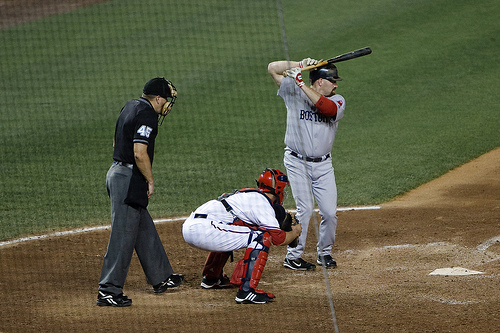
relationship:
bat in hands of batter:
[300, 46, 372, 71] [268, 57, 343, 272]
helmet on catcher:
[256, 168, 289, 206] [181, 162, 303, 296]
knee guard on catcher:
[244, 230, 273, 296] [181, 162, 303, 296]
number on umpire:
[137, 124, 153, 139] [96, 77, 185, 296]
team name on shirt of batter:
[299, 108, 328, 123] [268, 57, 343, 272]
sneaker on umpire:
[96, 292, 135, 307] [96, 77, 185, 296]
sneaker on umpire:
[156, 271, 184, 293] [96, 77, 185, 296]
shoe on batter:
[283, 258, 317, 273] [268, 57, 343, 272]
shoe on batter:
[317, 253, 336, 269] [268, 57, 343, 272]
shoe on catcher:
[236, 289, 270, 305] [181, 162, 303, 296]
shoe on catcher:
[202, 275, 234, 290] [181, 162, 303, 296]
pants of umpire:
[100, 163, 175, 295] [96, 77, 185, 296]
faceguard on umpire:
[158, 80, 177, 126] [96, 77, 185, 296]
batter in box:
[268, 57, 343, 272] [270, 242, 498, 278]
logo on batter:
[337, 98, 343, 107] [268, 57, 343, 272]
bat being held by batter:
[300, 46, 372, 71] [268, 57, 343, 272]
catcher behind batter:
[181, 162, 303, 296] [268, 57, 343, 272]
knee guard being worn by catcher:
[244, 230, 273, 296] [181, 162, 303, 296]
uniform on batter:
[278, 77, 347, 257] [268, 57, 343, 272]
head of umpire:
[141, 79, 168, 113] [96, 77, 185, 296]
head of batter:
[309, 65, 339, 96] [268, 57, 343, 272]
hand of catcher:
[292, 221, 302, 238] [181, 162, 303, 296]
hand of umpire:
[147, 179, 153, 199] [96, 77, 185, 296]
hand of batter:
[288, 68, 305, 88] [268, 57, 343, 272]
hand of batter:
[300, 58, 317, 71] [268, 57, 343, 272]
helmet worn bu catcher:
[256, 168, 289, 206] [181, 162, 303, 296]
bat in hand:
[300, 46, 372, 71] [288, 68, 305, 88]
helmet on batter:
[310, 63, 344, 83] [268, 57, 343, 272]